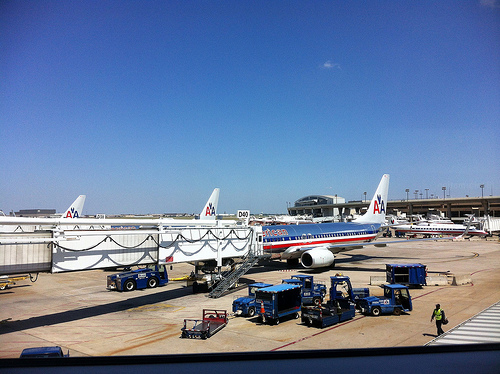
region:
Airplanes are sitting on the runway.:
[0, 160, 499, 285]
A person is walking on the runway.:
[424, 295, 451, 338]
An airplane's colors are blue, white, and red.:
[235, 170, 395, 275]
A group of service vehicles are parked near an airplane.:
[221, 252, 436, 332]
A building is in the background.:
[272, 167, 498, 237]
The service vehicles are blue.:
[100, 245, 451, 330]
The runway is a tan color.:
[0, 216, 499, 351]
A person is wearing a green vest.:
[425, 296, 450, 338]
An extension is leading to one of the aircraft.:
[0, 210, 275, 280]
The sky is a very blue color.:
[0, 47, 498, 208]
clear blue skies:
[90, 26, 182, 131]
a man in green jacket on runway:
[429, 305, 444, 324]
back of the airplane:
[366, 172, 396, 218]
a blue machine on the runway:
[113, 264, 163, 294]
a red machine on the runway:
[188, 300, 226, 337]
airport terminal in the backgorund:
[293, 195, 339, 217]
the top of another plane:
[63, 196, 86, 219]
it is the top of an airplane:
[194, 183, 224, 219]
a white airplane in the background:
[399, 221, 476, 233]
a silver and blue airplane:
[271, 222, 393, 248]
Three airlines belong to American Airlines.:
[48, 173, 413, 225]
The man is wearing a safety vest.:
[426, 300, 452, 333]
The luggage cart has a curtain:
[380, 261, 430, 290]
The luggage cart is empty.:
[254, 281, 303, 317]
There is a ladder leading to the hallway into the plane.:
[207, 248, 257, 293]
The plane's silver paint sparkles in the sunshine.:
[260, 220, 392, 247]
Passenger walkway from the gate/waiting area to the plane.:
[3, 226, 265, 268]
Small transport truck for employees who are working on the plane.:
[363, 283, 415, 315]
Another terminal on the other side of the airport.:
[285, 193, 350, 224]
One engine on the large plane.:
[296, 247, 345, 269]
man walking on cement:
[426, 297, 459, 341]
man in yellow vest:
[429, 295, 454, 335]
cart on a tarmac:
[174, 302, 250, 346]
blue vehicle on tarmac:
[356, 277, 436, 317]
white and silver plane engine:
[290, 237, 362, 280]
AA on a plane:
[368, 192, 400, 249]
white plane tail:
[354, 197, 421, 237]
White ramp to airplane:
[39, 218, 296, 263]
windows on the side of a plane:
[265, 218, 386, 238]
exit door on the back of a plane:
[361, 216, 397, 258]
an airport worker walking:
[428, 301, 450, 339]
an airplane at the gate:
[245, 170, 390, 270]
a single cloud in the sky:
[310, 52, 350, 82]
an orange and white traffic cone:
[255, 297, 265, 312]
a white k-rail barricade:
[445, 267, 472, 283]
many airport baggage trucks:
[176, 260, 423, 340]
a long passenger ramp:
[0, 220, 265, 271]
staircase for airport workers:
[201, 240, 271, 295]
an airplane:
[385, 210, 486, 235]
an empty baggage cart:
[176, 303, 229, 339]